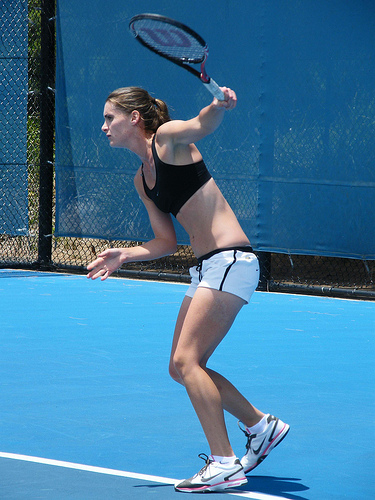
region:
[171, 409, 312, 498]
tennis shoes with socks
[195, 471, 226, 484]
nike logo on the side of a shoe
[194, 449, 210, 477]
laces on sneakers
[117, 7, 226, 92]
tennis racket with mesh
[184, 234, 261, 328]
black and white tennis shorts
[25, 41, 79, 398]
fence post on a tennis court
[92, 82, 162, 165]
lady with a serious face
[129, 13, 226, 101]
black and purple tennis racquet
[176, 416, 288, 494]
white pink and black sneakers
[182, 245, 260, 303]
black and white shorts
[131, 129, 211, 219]
black cotton sports bra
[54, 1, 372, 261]
blue tarp on fence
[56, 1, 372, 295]
metal chain link fence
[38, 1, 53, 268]
black metal fence pole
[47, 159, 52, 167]
metal hook on fence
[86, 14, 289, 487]
woman holding tennis racquet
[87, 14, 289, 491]
woman playing tennis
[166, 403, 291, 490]
sneakers on a tennis player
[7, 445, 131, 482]
white line painted on tennis court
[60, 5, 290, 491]
female tennis player on court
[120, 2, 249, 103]
tennis racket in woman's hand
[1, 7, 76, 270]
fence at a tennis court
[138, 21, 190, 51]
w on a tennis racket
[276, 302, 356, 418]
blue ground of a tennis court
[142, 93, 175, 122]
ponytail in woman's hair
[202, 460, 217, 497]
This woman has white and black shoes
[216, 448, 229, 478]
This woman has a Nike symbol on her socks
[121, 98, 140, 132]
This woman has a head full of brown hair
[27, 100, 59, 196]
There is a black pipe that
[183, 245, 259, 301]
shorts are worn by human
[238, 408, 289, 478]
sneaker is worn by human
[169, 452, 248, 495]
sneaker is worn by human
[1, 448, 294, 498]
line marks boundary on tennis court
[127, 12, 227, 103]
tennis racket is held by human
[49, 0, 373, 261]
tarp is attached to fence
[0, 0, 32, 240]
tarp is attached to fence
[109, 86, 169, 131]
hair is tied back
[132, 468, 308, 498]
shadow is created by tennis player